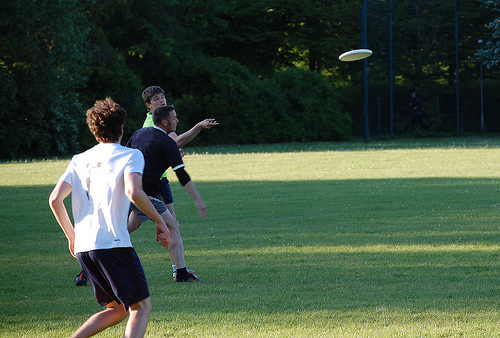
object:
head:
[84, 95, 129, 144]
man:
[48, 96, 171, 336]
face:
[150, 91, 167, 108]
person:
[139, 85, 219, 220]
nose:
[175, 117, 178, 122]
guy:
[70, 106, 210, 286]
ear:
[161, 118, 169, 128]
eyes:
[152, 95, 159, 102]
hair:
[84, 95, 127, 144]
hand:
[194, 117, 219, 132]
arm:
[121, 155, 166, 224]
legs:
[90, 248, 152, 337]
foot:
[171, 270, 203, 284]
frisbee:
[336, 49, 379, 63]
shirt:
[56, 141, 146, 254]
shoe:
[72, 269, 86, 287]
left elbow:
[47, 194, 65, 210]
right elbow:
[123, 184, 144, 205]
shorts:
[72, 248, 151, 310]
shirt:
[123, 124, 186, 197]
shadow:
[0, 174, 498, 338]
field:
[0, 137, 499, 338]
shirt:
[139, 110, 172, 180]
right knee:
[171, 217, 184, 232]